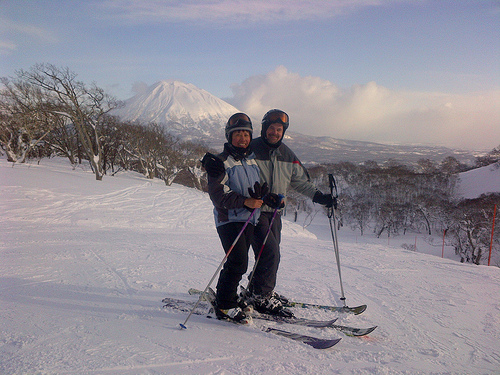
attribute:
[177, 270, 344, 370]
snow skis — pairs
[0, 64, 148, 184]
trees — barren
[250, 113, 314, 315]
man — dark gray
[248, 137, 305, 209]
jacket — light gray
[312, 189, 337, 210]
hand — one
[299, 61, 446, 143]
cloud — white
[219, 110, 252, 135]
helmet — ski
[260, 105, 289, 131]
helmet — ski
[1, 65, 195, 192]
trees — leafless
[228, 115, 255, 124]
ski googles — black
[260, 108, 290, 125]
goggles — snow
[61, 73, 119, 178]
trees — bare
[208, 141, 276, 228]
jacket — blue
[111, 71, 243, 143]
mountain — snow covered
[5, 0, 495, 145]
sky — blue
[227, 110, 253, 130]
goggles — snow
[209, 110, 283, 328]
woman — white, black